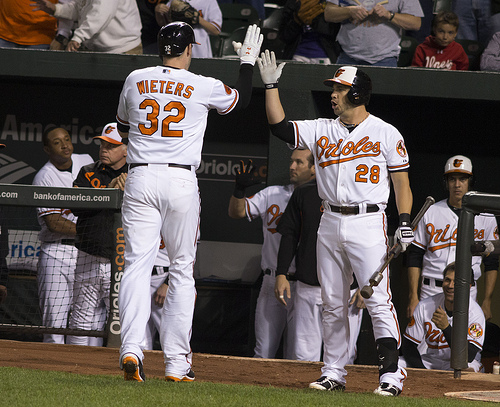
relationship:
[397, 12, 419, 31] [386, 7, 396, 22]
man's forearm and wristwatch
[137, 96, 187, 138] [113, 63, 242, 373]
number of a uniform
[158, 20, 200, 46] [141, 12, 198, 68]
helmet on head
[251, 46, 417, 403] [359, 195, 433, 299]
player holding bat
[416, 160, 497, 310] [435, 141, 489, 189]
player wearing a helmet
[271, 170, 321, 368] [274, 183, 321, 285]
man in a black shirt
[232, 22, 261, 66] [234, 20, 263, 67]
hand with glove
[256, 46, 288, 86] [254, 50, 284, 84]
hand with glove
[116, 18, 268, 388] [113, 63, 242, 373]
player in uniform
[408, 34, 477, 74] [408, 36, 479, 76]
boy wearing sweatshirt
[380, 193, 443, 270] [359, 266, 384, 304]
bat with weight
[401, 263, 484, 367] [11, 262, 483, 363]
player in dugout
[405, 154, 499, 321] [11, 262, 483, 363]
player in dugout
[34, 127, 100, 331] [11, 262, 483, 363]
player in dugout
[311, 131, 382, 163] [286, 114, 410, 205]
orioles logo on jersey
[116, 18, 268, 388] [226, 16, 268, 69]
player with hand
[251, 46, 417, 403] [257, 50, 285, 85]
player with hand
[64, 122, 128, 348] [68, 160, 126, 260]
man in jacket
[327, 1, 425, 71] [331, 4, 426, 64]
person in shirt